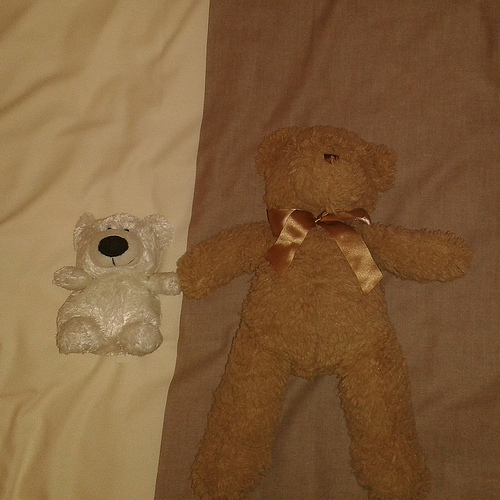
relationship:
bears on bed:
[67, 157, 412, 430] [139, 64, 223, 147]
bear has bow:
[178, 86, 450, 477] [254, 203, 431, 316]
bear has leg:
[178, 86, 477, 499] [302, 280, 403, 488]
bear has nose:
[178, 86, 477, 499] [273, 123, 432, 237]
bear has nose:
[178, 86, 477, 499] [307, 130, 372, 167]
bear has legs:
[40, 181, 180, 315] [38, 291, 188, 374]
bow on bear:
[240, 167, 397, 319] [197, 91, 453, 452]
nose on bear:
[310, 114, 371, 187] [135, 120, 438, 451]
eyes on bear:
[281, 123, 412, 193] [216, 124, 424, 466]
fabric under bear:
[198, 17, 473, 493] [125, 97, 473, 468]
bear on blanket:
[178, 86, 450, 477] [57, 5, 470, 458]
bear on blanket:
[178, 86, 477, 499] [154, 25, 463, 497]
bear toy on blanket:
[53, 210, 179, 354] [1, 2, 209, 499]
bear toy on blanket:
[175, 125, 469, 496] [154, 1, 498, 499]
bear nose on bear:
[95, 235, 127, 256] [50, 212, 180, 355]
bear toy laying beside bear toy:
[175, 125, 469, 496] [53, 210, 179, 354]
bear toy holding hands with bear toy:
[175, 125, 469, 496] [53, 210, 179, 354]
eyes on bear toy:
[104, 226, 131, 232] [53, 210, 179, 354]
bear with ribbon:
[178, 86, 477, 499] [263, 205, 383, 293]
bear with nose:
[50, 212, 180, 355] [98, 235, 129, 256]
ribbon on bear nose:
[263, 205, 383, 293] [95, 235, 127, 256]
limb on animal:
[151, 267, 182, 286] [154, 260, 199, 293]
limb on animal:
[117, 320, 159, 353] [49, 201, 191, 372]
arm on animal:
[162, 180, 270, 350] [165, 134, 483, 492]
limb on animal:
[161, 219, 272, 312] [165, 134, 483, 492]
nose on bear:
[37, 190, 184, 350] [52, 204, 173, 351]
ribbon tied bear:
[263, 205, 383, 293] [188, 124, 471, 472]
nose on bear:
[97, 217, 142, 263] [55, 199, 221, 379]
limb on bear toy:
[365, 223, 466, 281] [175, 125, 469, 496]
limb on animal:
[117, 320, 159, 353] [42, 203, 192, 363]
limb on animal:
[51, 315, 111, 359] [42, 203, 192, 363]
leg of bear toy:
[163, 347, 307, 498] [175, 125, 469, 496]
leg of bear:
[325, 332, 434, 498] [178, 86, 477, 499]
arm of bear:
[176, 208, 277, 294] [170, 106, 483, 486]